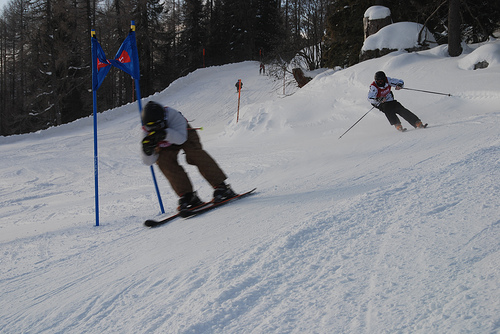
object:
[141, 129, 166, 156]
snow gear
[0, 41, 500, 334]
hill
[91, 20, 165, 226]
flag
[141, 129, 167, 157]
hands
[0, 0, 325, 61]
sky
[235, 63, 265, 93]
people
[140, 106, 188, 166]
shirt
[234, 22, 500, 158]
smooth snow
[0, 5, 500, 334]
rough snow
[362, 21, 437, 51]
snow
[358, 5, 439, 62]
building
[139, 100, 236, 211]
person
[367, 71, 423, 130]
person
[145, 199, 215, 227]
ski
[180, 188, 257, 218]
ski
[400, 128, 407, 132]
ski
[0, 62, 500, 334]
ski tracks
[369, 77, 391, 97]
red vest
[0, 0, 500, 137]
trees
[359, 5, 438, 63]
depth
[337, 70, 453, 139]
turn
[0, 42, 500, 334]
hill side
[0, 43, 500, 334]
slope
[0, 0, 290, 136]
branches